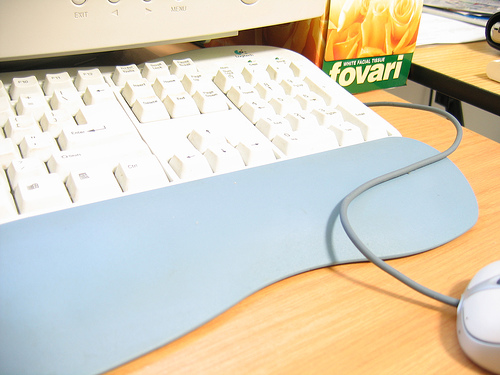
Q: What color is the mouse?
A: White.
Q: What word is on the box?
A: Fovari.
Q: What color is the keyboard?
A: White.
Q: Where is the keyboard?
A: On a desk.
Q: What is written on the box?
A: Fovari.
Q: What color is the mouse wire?
A: Grey.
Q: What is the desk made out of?
A: Wood.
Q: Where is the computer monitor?
A: Behind the keyboard.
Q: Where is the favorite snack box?
A: Next to the computer monitor.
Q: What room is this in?
A: An office.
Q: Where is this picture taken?
A: An office.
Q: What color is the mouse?
A: White.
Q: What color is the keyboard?
A: White and blue.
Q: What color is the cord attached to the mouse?
A: Grey.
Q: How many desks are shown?
A: Two.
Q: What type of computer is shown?
A: Desktop.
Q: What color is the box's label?
A: Green and white.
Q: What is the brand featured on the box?
A: Fovari.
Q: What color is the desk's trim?
A: Black.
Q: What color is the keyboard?
A: White.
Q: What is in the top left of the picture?
A: The bottom of a monitor.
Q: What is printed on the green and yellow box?
A: 'Fovari'.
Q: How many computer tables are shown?
A: Two.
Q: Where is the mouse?
A: The bottom right.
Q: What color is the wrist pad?
A: Blue.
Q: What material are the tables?
A: Wood.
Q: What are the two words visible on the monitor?
A: 'Exit' and 'Menu'.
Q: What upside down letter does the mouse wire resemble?
A: An 'S'.